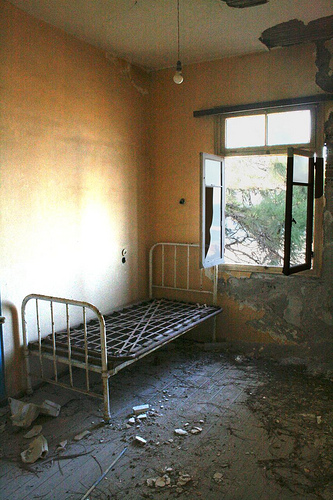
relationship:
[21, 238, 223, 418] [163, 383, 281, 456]
bed on floor.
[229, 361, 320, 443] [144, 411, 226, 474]
dirt on floor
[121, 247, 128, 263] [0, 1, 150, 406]
outlet on wall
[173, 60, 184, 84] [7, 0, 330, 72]
bulb hanging down from ceiling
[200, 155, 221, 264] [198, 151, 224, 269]
broken window in wood frame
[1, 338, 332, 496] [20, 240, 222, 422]
ground beneath bed frame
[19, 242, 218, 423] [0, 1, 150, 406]
bed frame by wall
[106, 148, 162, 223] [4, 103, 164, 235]
shadow on wall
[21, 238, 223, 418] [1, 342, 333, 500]
bed on bottom of ground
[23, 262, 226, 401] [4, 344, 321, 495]
bed on bottom of floor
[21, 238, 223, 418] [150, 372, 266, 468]
bed on bottom of floor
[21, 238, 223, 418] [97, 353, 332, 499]
bed on bottom of floor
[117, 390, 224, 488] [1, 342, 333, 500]
broken plaster on ground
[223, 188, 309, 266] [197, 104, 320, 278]
tree growing outside window